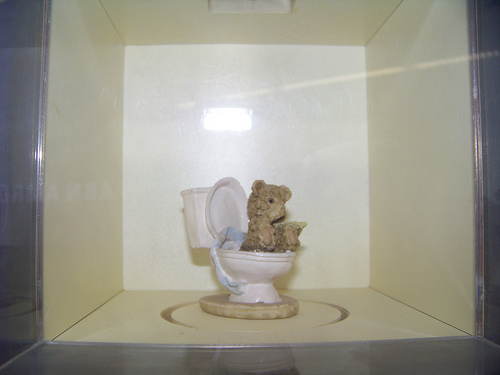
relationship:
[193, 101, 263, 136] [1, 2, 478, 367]
light on wall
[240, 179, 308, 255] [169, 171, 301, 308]
bear on toilet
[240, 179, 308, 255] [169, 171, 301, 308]
bear and toilet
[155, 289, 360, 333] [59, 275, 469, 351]
circle on ground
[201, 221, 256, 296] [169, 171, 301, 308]
ribbon on toilet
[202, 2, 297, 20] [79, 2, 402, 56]
vent on ceiling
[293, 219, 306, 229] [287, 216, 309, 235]
edge of cup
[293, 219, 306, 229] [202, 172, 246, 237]
edge of lid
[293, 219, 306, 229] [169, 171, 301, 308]
edge of toilet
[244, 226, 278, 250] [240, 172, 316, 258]
leg of doll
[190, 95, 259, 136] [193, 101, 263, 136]
reflection of light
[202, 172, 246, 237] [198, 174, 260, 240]
lid pushed up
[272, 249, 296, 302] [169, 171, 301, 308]
front of toilet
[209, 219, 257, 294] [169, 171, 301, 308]
blanket on toilet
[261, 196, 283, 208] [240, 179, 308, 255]
eye of bear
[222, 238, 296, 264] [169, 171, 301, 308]
bowl of toilet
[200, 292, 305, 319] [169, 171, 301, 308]
platform under toilet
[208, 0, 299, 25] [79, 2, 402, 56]
square in ceiling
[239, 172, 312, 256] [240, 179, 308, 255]
brown teddy bear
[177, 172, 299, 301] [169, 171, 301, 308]
miniature a toilet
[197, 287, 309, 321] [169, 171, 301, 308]
base of toilet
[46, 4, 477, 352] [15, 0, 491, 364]
glass in display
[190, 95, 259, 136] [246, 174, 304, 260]
reflection of body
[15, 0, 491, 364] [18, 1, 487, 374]
display metal case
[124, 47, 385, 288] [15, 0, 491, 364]
interior of display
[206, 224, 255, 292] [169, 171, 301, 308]
blue from toilet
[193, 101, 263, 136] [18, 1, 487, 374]
light in case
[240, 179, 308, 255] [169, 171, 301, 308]
bear in toilet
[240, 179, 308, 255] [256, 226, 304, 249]
bear has pads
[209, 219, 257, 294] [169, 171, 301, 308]
blanket involved toilet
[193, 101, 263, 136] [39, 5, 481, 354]
light on scene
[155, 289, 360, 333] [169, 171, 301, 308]
circle surrounds toilet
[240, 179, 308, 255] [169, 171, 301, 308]
bear into toilet